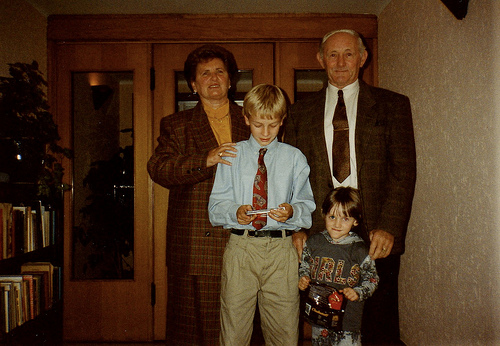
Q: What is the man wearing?
A: Jacket.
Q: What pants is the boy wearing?
A: Dress.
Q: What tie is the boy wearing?
A: Long tie.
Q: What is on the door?
A: Glass.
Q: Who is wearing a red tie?
A: Boy with blonde hair.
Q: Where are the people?
A: In a house.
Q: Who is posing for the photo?
A: Four people.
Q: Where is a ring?
A: On woman's finger.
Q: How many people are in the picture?
A: Four.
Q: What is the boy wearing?
A: A tie.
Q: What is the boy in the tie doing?
A: Looking down.